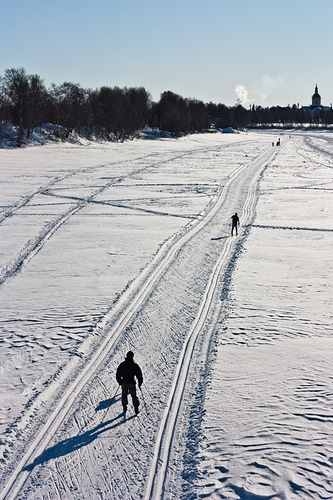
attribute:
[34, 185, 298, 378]
snow — packed, white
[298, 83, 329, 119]
building — pointy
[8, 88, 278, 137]
trees — brown, border, deciduous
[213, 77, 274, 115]
cloud — small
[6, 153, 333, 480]
field — large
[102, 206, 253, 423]
people — skiing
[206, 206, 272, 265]
person — skiing